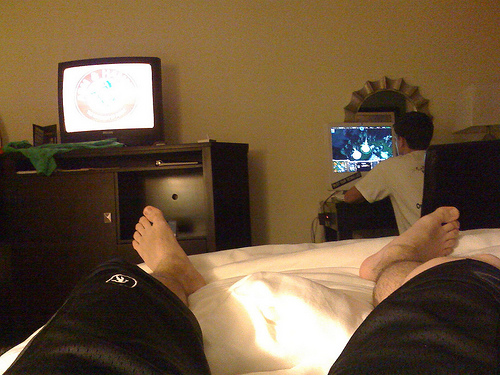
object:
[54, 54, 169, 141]
television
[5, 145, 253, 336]
cabinet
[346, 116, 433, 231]
boy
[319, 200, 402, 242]
desk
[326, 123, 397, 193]
computer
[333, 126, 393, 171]
screen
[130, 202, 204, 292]
feet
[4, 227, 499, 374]
bed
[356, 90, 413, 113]
mirror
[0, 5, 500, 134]
wall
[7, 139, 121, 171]
cloth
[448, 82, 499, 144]
lamp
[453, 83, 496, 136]
shade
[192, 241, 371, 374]
sheet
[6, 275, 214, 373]
legs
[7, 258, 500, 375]
shorts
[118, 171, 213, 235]
an open section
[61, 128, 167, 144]
black edge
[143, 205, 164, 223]
toes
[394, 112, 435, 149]
boy's hair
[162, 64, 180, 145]
shadow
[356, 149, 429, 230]
short sleeves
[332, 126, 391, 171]
game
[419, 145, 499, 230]
chair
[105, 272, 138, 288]
white lettering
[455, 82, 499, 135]
lampshade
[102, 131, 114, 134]
lettering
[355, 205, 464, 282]
foot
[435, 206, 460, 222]
toes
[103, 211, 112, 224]
knob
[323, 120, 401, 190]
monitor